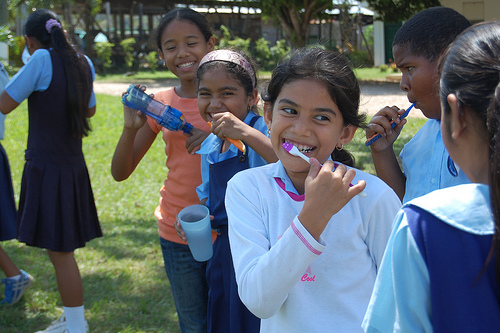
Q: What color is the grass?
A: Green.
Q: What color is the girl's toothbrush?
A: White and purple.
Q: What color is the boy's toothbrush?
A: Blue and orange.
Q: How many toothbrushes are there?
A: Two.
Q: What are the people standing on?
A: The grass.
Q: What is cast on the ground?
A: Shadows.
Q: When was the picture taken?
A: Daytime.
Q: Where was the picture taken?
A: School yard.